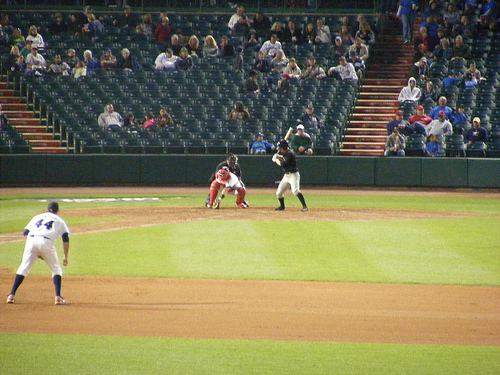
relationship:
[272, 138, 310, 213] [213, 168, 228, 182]
man wearing baseball cap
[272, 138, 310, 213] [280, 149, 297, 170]
man wearing shirt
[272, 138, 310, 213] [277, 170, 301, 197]
man wearing pants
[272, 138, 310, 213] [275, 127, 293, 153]
man holding baseball bat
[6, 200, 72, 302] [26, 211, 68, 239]
man wearing shirt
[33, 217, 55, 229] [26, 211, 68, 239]
number printed on shirt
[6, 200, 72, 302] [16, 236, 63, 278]
man wearing pants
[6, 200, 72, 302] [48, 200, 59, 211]
man wearing cap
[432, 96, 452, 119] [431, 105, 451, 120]
spectator wearing shirt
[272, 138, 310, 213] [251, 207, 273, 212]
man standing at home plate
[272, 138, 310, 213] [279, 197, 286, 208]
man wearing sock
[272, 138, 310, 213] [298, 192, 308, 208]
man wearing sock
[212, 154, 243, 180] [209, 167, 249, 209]
umpire behind catcher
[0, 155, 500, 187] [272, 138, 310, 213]
wall behind man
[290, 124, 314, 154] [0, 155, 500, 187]
person standing behind wall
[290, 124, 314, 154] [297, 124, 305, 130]
person wearing hat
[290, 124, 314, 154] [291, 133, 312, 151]
person wearing shirt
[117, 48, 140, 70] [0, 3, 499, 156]
person sitting in stands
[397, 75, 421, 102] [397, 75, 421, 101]
person wearing hoodie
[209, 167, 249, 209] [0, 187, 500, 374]
catcher on surface of baseball field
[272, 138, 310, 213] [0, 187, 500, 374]
man on surface of baseball field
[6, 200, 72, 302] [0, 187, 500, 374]
man on surface of baseball field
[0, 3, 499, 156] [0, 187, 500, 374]
stands behind baseball field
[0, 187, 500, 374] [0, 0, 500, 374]
baseball field inside stadium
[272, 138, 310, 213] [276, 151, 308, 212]
man wearing baseball uniform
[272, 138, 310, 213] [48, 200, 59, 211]
man wearing cap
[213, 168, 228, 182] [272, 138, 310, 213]
baseball cap on top of man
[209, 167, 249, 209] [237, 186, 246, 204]
catcher wearing shinguard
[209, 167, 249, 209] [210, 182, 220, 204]
catcher wearing shinguard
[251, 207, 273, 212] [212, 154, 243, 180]
home plate near umpire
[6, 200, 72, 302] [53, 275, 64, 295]
man wearing sock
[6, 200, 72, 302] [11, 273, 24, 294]
man wearing sock